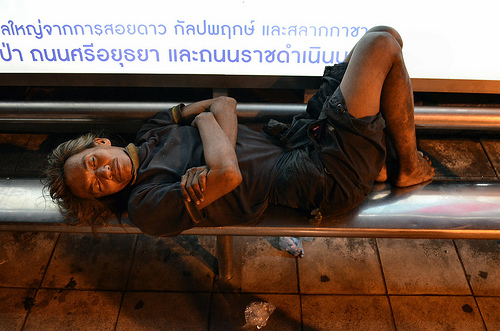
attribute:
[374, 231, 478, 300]
tile — brown, square, large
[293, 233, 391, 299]
tile — brown, square, large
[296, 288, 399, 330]
tile — brown, square, large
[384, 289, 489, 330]
tile — brown, square, large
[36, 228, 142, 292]
tile — brown, square, large